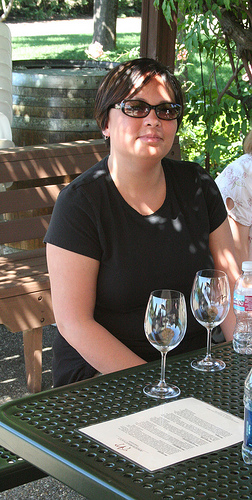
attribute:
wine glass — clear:
[187, 269, 234, 365]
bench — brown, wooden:
[1, 135, 202, 366]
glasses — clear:
[138, 267, 234, 399]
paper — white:
[72, 391, 250, 472]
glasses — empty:
[140, 268, 222, 372]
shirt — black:
[40, 151, 231, 349]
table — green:
[212, 349, 230, 364]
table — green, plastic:
[0, 333, 251, 497]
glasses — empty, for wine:
[143, 288, 188, 398]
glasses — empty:
[190, 268, 231, 370]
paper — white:
[77, 389, 242, 470]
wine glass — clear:
[140, 283, 188, 379]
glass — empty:
[141, 288, 187, 402]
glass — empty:
[189, 264, 232, 374]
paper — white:
[78, 394, 242, 484]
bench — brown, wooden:
[0, 133, 180, 394]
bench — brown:
[0, 289, 57, 339]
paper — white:
[221, 411, 235, 429]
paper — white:
[68, 387, 250, 477]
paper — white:
[84, 393, 212, 467]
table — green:
[52, 378, 113, 440]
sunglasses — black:
[119, 98, 186, 119]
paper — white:
[73, 396, 244, 473]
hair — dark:
[93, 53, 186, 129]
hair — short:
[93, 57, 184, 148]